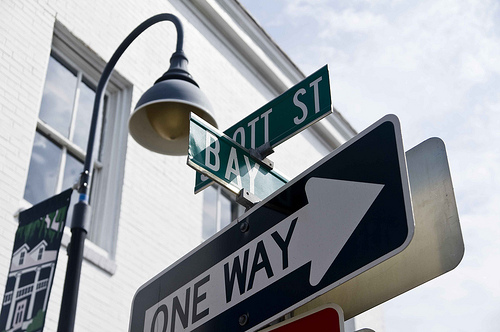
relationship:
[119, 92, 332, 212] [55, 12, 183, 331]
sign on pole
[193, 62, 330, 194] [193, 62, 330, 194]
sign show sign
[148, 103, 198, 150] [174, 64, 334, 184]
light next to sign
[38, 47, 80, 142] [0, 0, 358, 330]
window on brick building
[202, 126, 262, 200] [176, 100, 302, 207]
word on sign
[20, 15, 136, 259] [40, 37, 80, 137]
window has pane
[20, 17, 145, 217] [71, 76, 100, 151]
window has pane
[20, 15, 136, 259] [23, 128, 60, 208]
window has pane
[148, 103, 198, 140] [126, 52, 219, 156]
light inside globe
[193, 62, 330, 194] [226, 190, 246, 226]
sign on pole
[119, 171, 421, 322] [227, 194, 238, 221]
sign on pole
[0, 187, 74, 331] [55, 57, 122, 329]
banner on pole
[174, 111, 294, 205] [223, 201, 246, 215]
sign on pole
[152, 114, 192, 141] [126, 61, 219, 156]
bulb in lamp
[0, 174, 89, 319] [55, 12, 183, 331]
banner on pole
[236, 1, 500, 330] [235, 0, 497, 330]
cloud in sky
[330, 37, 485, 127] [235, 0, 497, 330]
cloud in sky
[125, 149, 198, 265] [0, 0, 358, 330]
wall on brick building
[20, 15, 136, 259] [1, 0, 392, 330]
window on brick building